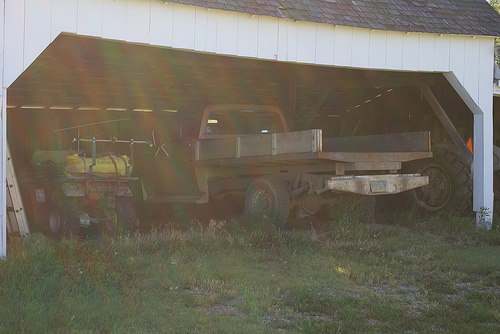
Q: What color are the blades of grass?
A: Green.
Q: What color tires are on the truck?
A: Black.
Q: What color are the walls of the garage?
A: White.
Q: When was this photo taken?
A: Day time.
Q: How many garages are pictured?
A: One.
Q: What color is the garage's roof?
A: Black.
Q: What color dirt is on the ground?
A: Grey.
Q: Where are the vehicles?
A: In the garage.